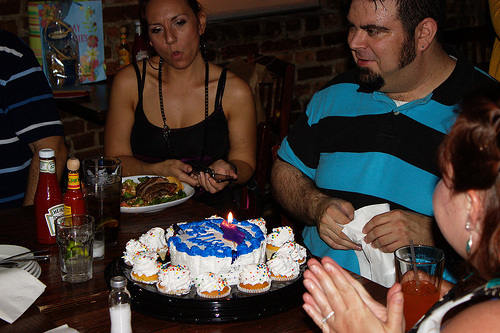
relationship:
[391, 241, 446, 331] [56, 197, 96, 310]
glass of orange soda or juice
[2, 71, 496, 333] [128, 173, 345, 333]
family singing happy birthday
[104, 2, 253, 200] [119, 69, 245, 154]
woman wearing black tank top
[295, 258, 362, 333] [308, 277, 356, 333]
woman with engagement ring on left ring finger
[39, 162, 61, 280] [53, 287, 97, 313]
ketchup and hot sauce on table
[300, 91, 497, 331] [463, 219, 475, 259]
woman wearing silver earrings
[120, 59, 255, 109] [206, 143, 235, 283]
woman with cellphone in her left hand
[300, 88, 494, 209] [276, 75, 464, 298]
black and blue striped shirt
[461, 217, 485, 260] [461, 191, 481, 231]
earring in womans ear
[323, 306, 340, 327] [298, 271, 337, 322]
ring in womans finger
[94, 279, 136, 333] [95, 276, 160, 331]
clear gray and white salt shaker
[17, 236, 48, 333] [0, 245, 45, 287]
stack of white plates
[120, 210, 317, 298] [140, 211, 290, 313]
cupcakes with white frosting and sprinkles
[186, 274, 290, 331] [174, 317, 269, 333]
table made of wood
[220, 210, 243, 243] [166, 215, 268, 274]
candle lit on cake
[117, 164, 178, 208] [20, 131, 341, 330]
plate of food on table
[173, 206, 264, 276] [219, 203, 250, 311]
birthday cake with a single candle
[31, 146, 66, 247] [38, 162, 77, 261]
bottle of heinz ketchup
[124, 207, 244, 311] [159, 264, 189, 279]
cupcakes with multi colored sprinkles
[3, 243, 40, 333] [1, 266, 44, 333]
stack of plates covered with a napkin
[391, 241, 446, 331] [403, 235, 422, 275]
glass has straw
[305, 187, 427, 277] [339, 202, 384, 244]
hands holding napkin